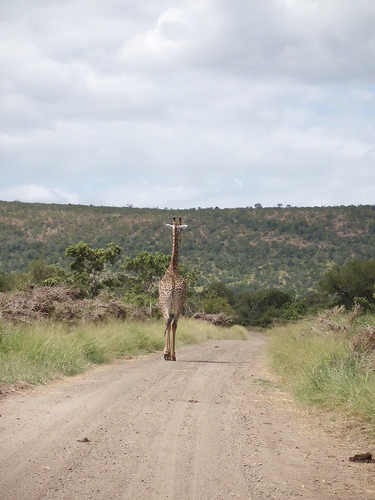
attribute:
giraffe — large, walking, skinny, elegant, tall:
[155, 217, 186, 361]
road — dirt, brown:
[1, 325, 373, 496]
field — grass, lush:
[263, 305, 374, 425]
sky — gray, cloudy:
[1, 1, 373, 209]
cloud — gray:
[107, 1, 373, 87]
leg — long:
[170, 314, 180, 362]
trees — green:
[64, 240, 121, 302]